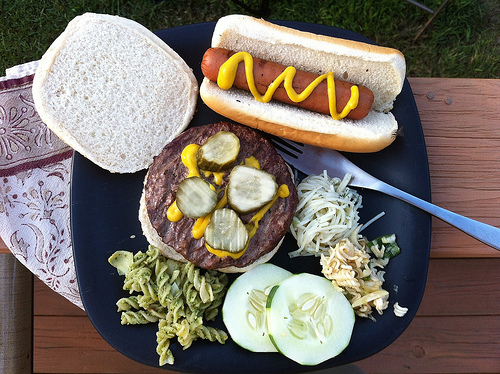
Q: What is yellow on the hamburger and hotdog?
A: Mustard.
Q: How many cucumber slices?
A: Two.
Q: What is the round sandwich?
A: A hamburger.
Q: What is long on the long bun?
A: A hotdog.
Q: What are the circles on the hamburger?
A: Pickles.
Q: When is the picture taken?
A: Daytime.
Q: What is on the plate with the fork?
A: Food.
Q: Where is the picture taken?
A: At a picnic.